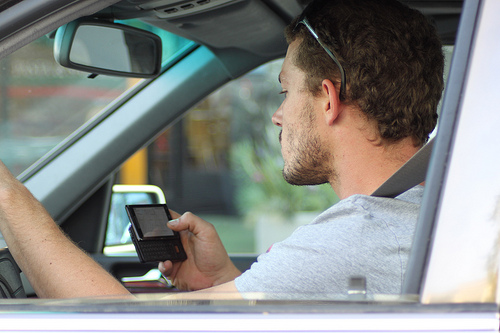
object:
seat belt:
[370, 135, 435, 197]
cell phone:
[126, 203, 187, 262]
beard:
[273, 96, 338, 190]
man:
[0, 0, 446, 301]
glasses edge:
[299, 17, 347, 102]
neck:
[326, 147, 429, 200]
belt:
[364, 131, 434, 199]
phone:
[123, 203, 186, 265]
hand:
[156, 205, 231, 292]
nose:
[268, 96, 286, 126]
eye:
[276, 87, 293, 98]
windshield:
[0, 19, 202, 179]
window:
[18, 17, 436, 309]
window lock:
[348, 276, 366, 303]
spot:
[363, 213, 376, 222]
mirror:
[67, 23, 163, 75]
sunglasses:
[287, 5, 350, 101]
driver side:
[2, 3, 472, 330]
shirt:
[231, 185, 424, 295]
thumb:
[166, 210, 216, 235]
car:
[2, 3, 498, 331]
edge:
[370, 111, 420, 181]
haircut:
[287, 3, 446, 145]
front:
[0, 12, 196, 185]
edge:
[337, 68, 351, 105]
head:
[270, 3, 446, 186]